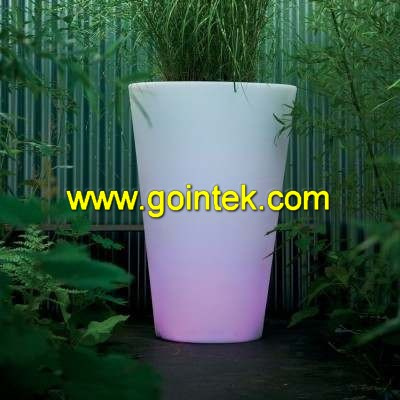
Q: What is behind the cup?
A: Bush.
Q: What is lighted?
A: The cup.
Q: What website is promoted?
A: Www.gointek.com.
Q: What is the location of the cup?
A: Surrounded by foliage.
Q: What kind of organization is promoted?
A: Company.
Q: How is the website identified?
A: Yellow letters.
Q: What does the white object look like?
A: Cup.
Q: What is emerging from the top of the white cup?
A: Plant.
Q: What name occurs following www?
A: Gointek.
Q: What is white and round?
A: Planter.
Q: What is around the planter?
A: Green foliage.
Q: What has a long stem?
A: Plant.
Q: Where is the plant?
A: Next to the white thing.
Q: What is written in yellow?
A: Name of a website.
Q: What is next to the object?
A: Dirt.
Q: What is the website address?
A: Gointek.com.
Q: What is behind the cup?
A: Fence.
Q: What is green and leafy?
A: Tree.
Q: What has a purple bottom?
A: Cup.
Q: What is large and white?
A: Cup.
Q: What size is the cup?
A: Large.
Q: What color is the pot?
A: White.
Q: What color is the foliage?
A: Green.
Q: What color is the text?
A: Yellow.